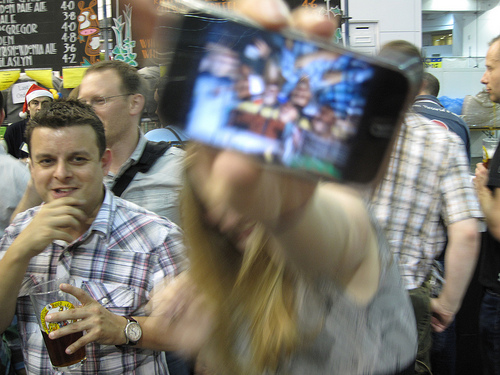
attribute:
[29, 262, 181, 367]
hand — brown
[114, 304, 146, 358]
watch — brown, big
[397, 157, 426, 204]
shirt — plaid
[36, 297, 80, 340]
decal — yellow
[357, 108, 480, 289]
shirt — plaid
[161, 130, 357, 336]
hair — blonde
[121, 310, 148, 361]
watch — brown, big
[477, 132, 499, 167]
glass — beer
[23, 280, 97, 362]
glass — beer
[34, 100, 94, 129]
hair — brown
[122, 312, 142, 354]
watch — big, brown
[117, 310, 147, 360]
watch — big, brown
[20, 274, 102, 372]
glass — drinking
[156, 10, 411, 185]
cell phone — on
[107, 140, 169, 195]
strap — black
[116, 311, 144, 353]
watch — brown, big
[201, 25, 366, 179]
screen — moving, blurry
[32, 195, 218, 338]
shirt — brown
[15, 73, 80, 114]
hat — red and white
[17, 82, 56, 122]
hat — santa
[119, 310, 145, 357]
watch — big